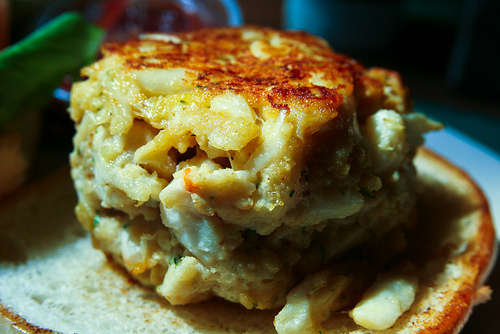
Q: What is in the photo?
A: Crab cake.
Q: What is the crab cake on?
A: Bread.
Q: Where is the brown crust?
A: On top of the crab cake.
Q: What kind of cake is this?
A: Crab.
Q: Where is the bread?
A: Under the crab cake.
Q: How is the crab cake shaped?
A: Rounded.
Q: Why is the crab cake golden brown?
A: Has been cooked.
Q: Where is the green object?
A: To the left of the cake.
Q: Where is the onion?
A: Bottom right.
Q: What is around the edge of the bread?
A: Toasted crust.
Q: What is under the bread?
A: A blue plate.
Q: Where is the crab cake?
A: On the bread.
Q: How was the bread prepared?
A: It was toasted.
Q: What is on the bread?
A: The crab cake.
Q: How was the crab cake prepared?
A: It was fried.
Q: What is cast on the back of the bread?
A: Shadow.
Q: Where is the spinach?
A: In the crab cake.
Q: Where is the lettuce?
A: Behind the crab cake.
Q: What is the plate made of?
A: Porcelain.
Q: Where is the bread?
A: Under the stuffing?.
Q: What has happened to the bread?
A: It is toasted.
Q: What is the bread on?
A: A plate.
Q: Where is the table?
A: Under the plate.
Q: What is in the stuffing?
A: Eggs.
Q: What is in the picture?
A: Food.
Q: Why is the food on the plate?
A: For eating.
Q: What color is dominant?
A: Brown.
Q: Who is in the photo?
A: No one.